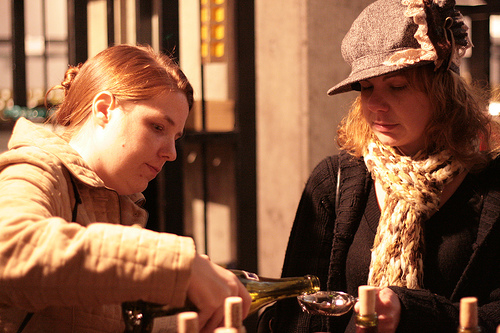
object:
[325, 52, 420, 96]
brim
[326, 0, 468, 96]
brown hat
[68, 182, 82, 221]
strap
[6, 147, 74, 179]
shoulder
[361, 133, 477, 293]
scarf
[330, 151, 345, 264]
strap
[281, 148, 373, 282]
shoulder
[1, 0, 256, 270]
doors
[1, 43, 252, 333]
woman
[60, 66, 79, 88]
bun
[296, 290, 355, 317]
glass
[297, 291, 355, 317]
bowl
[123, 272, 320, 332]
bottle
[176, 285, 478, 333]
corks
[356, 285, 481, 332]
bottles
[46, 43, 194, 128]
hair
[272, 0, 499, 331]
woman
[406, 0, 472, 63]
decoration